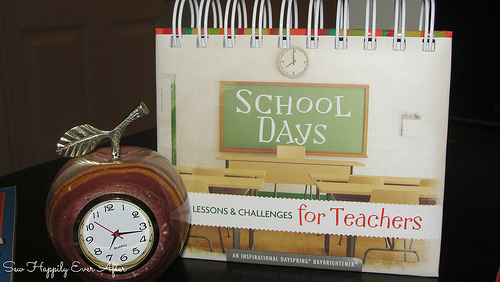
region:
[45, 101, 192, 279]
clock is shaped like an apple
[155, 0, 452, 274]
Daily calendar for teachers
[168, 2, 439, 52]
white binding on daily calendar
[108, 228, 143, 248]
black hands on a desk clock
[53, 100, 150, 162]
gold leaf and stem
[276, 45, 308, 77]
white clock hanging on the wall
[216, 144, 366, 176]
wooden teachers desk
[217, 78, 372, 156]
green chalk board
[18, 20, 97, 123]
paneling on the wall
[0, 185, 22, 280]
corner of blue book on desk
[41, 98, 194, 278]
an apple shaped clock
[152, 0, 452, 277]
a small spiral bound book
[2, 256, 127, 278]
white cursive lettering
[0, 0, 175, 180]
a light colored wooden door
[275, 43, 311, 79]
a picture of a clock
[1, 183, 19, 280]
the corner of a book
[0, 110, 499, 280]
a black table top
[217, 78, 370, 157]
a green chalkboard with writing on it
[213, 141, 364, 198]
a tan desk and chair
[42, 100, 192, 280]
a fancy decorative clock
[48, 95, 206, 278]
an apple clock to keep up with the time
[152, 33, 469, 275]
a planner for teachers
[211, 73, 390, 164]
a chalk board that says school days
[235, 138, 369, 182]
desk where the teacher sits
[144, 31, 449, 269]
lessons and challenges book for the teacher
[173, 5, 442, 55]
wire bindings for the planner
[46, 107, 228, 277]
a red clock in the shape of an apple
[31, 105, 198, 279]
clock on a desk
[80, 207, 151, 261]
face on the clock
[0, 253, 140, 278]
branding on the image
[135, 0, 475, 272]
binder book with material inside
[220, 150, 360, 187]
desk in the image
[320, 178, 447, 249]
desk and chairs in image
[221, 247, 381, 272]
details of the book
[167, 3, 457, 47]
rings holding contents together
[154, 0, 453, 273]
one spiraled rectangular shaped book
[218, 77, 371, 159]
little white lettered SCHOOL DAYS sign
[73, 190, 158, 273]
one round white clock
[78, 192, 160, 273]
white clock with black numbers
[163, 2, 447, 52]
large white metal spirals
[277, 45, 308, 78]
picture of round white clock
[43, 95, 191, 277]
ceramic apple clock with green metal stem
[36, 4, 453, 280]
little clock next to book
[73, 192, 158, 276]
round clock reading 7:17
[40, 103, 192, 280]
an apple with a clock on it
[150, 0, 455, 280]
a spiral bound book for teachers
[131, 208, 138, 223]
a number on the clock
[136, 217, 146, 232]
a number on the clock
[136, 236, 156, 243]
a number on the clock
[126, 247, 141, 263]
a number on the clock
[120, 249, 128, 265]
a number on the clock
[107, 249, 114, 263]
a number on the clock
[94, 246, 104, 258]
a number on the clock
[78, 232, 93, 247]
a number on the clock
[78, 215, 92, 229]
a number on the clock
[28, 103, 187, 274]
clock on table top